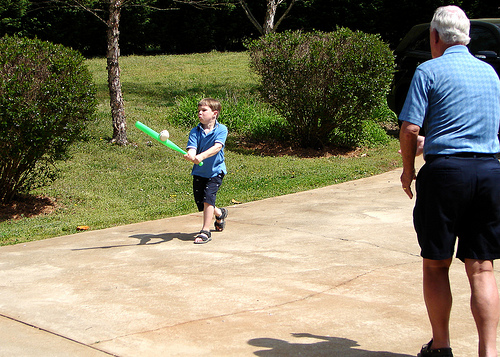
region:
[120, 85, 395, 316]
the boy is swinging a bat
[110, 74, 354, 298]
the boy is holding a green bat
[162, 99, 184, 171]
the boy is hitting a white ball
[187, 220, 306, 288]
the boy is wearing sandals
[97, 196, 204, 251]
the boy's shadow is on the ground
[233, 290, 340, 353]
the man's shadow is on the ground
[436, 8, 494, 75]
the man has silver hair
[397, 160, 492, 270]
the man is wearing dark shorts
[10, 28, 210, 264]
the bush is green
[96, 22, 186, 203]
the tree trunk is rough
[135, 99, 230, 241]
a boy playing baseball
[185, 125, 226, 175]
boy wearing a blue shirt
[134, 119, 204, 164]
a green baseball bat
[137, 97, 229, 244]
a boy about to hit a ball with a baseball bat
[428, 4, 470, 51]
a man with white hair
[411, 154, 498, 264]
a man with blue shorts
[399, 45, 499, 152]
man wearing a blue shirt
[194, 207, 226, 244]
boy wearing black sandals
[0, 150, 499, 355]
a driveway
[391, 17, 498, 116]
a parked black car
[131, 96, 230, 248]
A LITTLE BOY HITTING A BALL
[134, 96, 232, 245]
A LITTLE BOY HOLDING A BAT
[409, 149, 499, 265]
A PAIR OF BLUE SHORTS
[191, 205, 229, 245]
A PAIR OF SANDALS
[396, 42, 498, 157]
A MANS BLUE SHIRT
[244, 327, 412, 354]
A SHADOW ON THE GROUND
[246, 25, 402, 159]
A BUSH ON THE GRASS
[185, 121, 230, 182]
A LITTLE BOYS BLUE SHIRT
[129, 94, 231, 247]
A BOY SWINGING A BAT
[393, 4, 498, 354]
A MAN WITH GRAY HAIR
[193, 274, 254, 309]
Part of the ground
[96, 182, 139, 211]
Part of the green grass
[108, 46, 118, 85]
Part of the tree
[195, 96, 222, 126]
The head of the person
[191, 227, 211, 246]
The left foot of the boy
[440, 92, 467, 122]
Part of the shirt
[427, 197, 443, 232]
Part of the shorts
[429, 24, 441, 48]
The left ear of the person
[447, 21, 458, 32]
Part of the hair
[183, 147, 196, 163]
The right hand of the boy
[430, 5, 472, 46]
a man's short cut gray hair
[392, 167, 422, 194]
the hand of a man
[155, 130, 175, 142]
a white baseball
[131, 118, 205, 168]
a green baseball bat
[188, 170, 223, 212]
a boy's blue shorts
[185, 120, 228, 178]
a boy's blue shirt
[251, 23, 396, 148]
a large green bush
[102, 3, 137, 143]
a tree branch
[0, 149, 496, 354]
part of a driveway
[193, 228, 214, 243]
a boy's sandal